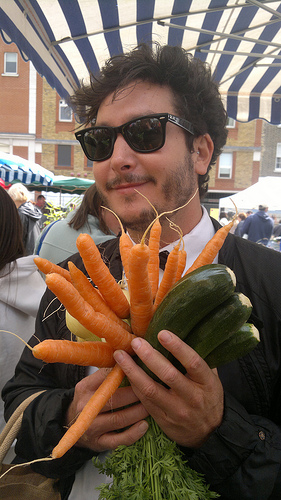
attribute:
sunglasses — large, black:
[73, 112, 204, 163]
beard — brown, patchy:
[130, 148, 192, 232]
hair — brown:
[71, 41, 230, 195]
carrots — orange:
[28, 188, 235, 459]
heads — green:
[95, 417, 224, 499]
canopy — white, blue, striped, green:
[1, 3, 280, 130]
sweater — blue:
[234, 212, 277, 235]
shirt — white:
[127, 207, 219, 268]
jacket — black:
[1, 225, 277, 499]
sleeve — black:
[179, 391, 280, 497]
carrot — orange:
[186, 212, 248, 263]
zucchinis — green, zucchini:
[145, 261, 263, 370]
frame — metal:
[25, 0, 280, 86]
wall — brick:
[38, 77, 258, 191]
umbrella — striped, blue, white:
[1, 151, 57, 189]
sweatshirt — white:
[1, 256, 49, 382]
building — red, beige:
[1, 34, 263, 189]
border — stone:
[25, 62, 38, 160]